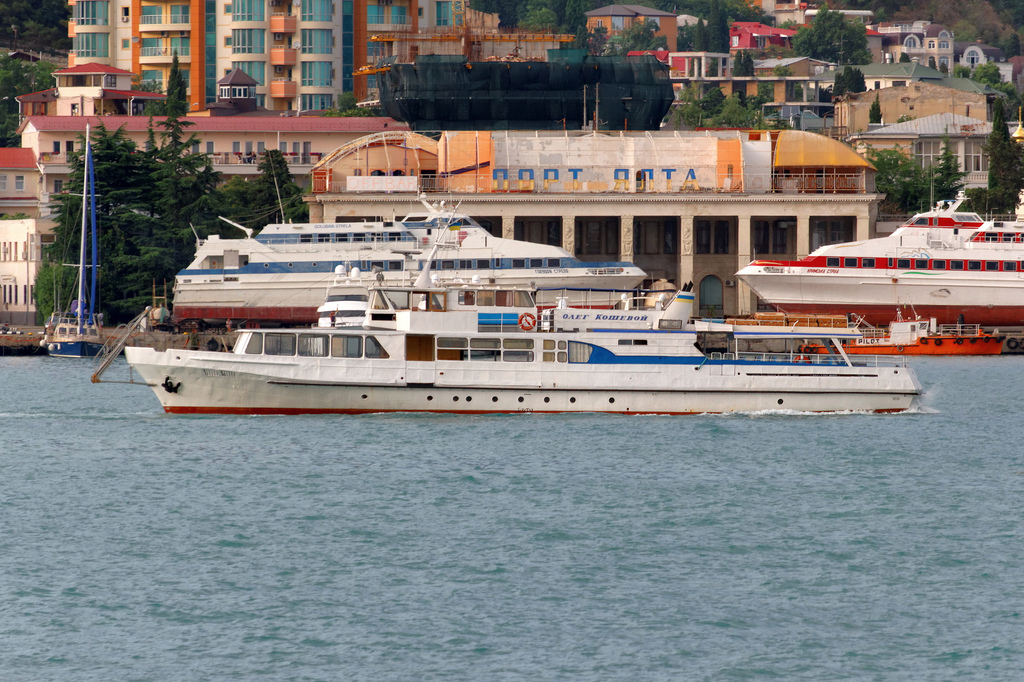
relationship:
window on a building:
[292, 43, 332, 87] [61, 2, 425, 117]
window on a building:
[289, 73, 337, 106] [58, 6, 486, 132]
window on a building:
[61, 66, 113, 99] [58, 6, 422, 147]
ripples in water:
[54, 408, 966, 668] [4, 346, 992, 679]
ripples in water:
[43, 397, 1007, 661] [4, 346, 992, 679]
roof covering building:
[15, 111, 407, 137] [17, 109, 407, 166]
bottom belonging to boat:
[160, 402, 930, 418] [121, 188, 923, 417]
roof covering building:
[773, 128, 879, 170] [300, 121, 890, 316]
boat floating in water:
[799, 303, 992, 358] [4, 346, 992, 679]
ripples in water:
[502, 525, 652, 621] [280, 452, 873, 656]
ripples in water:
[154, 431, 669, 607] [211, 446, 318, 524]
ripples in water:
[152, 588, 377, 647] [49, 465, 484, 671]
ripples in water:
[109, 428, 192, 506] [8, 420, 864, 671]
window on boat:
[260, 335, 299, 362] [126, 275, 926, 427]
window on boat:
[299, 329, 332, 360] [126, 275, 926, 427]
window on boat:
[329, 329, 368, 360] [126, 275, 926, 427]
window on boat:
[370, 331, 397, 360] [126, 275, 926, 427]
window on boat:
[405, 335, 431, 364] [124, 260, 918, 429]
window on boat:
[437, 340, 468, 366] [124, 260, 918, 429]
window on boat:
[470, 338, 505, 360] [126, 275, 926, 427]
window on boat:
[492, 335, 538, 357] [126, 275, 926, 427]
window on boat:
[548, 340, 572, 373] [111, 279, 919, 418]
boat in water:
[68, 298, 969, 484] [23, 350, 987, 640]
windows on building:
[598, 173, 648, 327] [118, 9, 758, 455]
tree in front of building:
[60, 121, 153, 377] [52, 29, 496, 453]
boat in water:
[68, 298, 969, 484] [73, 344, 866, 634]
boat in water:
[136, 204, 867, 485] [99, 266, 938, 627]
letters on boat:
[436, 284, 631, 419] [147, 217, 908, 540]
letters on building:
[473, 109, 549, 207] [179, 42, 869, 531]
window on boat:
[393, 320, 446, 377] [86, 256, 899, 566]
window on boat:
[576, 307, 616, 405] [132, 221, 964, 550]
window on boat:
[339, 314, 422, 442] [140, 253, 927, 571]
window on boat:
[442, 297, 525, 414] [142, 152, 936, 639]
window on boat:
[412, 297, 469, 393] [179, 230, 992, 639]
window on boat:
[386, 305, 492, 409] [175, 268, 923, 562]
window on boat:
[514, 282, 592, 389] [86, 256, 899, 566]